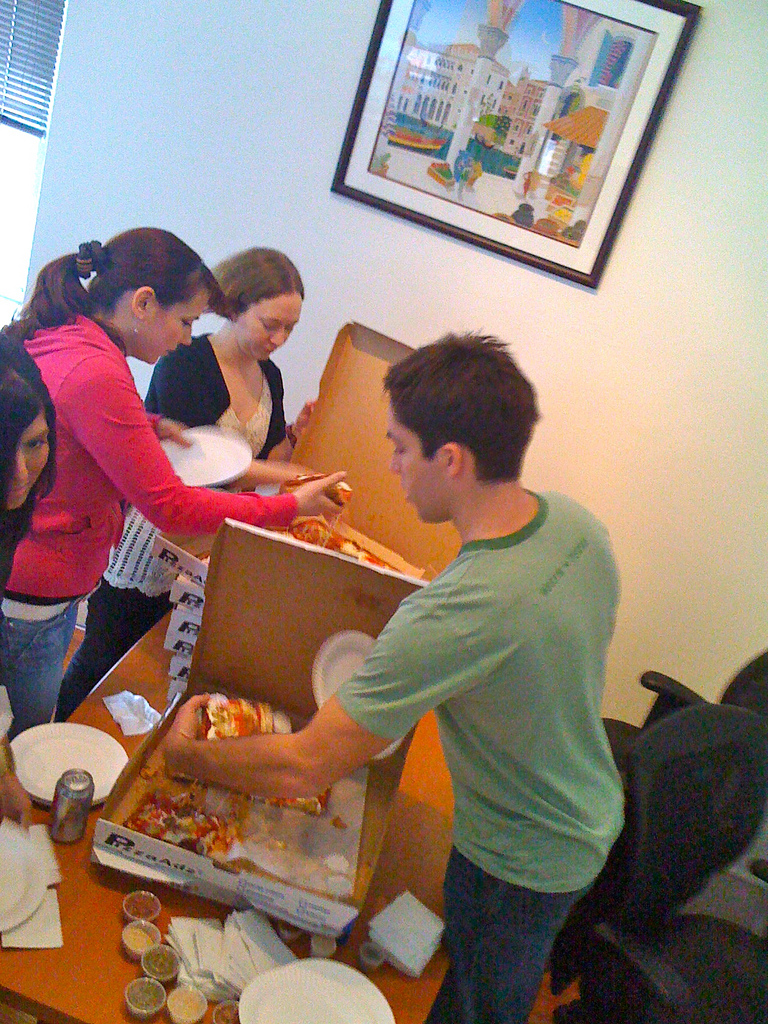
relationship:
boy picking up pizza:
[165, 332, 625, 1022] [170, 657, 309, 862]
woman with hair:
[10, 335, 100, 679] [1, 322, 62, 539]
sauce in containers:
[111, 886, 182, 1001] [92, 890, 263, 1012]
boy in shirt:
[165, 332, 625, 1022] [296, 518, 675, 910]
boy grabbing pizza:
[165, 332, 625, 1022] [145, 657, 348, 837]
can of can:
[29, 747, 121, 879] [51, 767, 95, 839]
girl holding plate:
[0, 227, 352, 744] [156, 420, 271, 517]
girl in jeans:
[0, 210, 275, 778] [7, 576, 118, 729]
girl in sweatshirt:
[0, 210, 275, 778] [8, 294, 331, 623]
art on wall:
[331, 0, 702, 288] [64, 20, 751, 713]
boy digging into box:
[329, 300, 675, 928] [107, 508, 465, 971]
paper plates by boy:
[244, 965, 390, 1016] [165, 332, 625, 1022]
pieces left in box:
[175, 776, 282, 845] [89, 517, 430, 938]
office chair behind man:
[583, 702, 746, 996] [374, 388, 618, 963]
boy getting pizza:
[165, 332, 625, 1022] [136, 684, 282, 820]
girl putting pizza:
[0, 227, 352, 744] [251, 447, 379, 523]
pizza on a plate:
[251, 447, 379, 523] [153, 412, 236, 495]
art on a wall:
[331, 0, 702, 288] [104, 28, 730, 622]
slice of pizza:
[149, 792, 204, 835] [170, 725, 354, 864]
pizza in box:
[170, 725, 354, 864] [115, 669, 457, 948]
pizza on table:
[116, 673, 375, 893] [3, 546, 537, 1022]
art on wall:
[340, 6, 707, 283] [11, 2, 762, 729]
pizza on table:
[124, 692, 332, 862] [3, 546, 537, 1022]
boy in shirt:
[165, 332, 625, 1022] [333, 485, 631, 891]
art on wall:
[331, 0, 702, 288] [11, 2, 762, 729]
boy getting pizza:
[165, 332, 625, 1022] [124, 692, 332, 862]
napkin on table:
[369, 890, 444, 969] [3, 546, 537, 1022]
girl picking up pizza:
[0, 227, 352, 744] [275, 471, 353, 501]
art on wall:
[331, 0, 702, 288] [6, 3, 762, 1004]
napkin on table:
[102, 687, 163, 734] [3, 546, 537, 1022]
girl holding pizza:
[0, 227, 352, 744] [278, 477, 353, 517]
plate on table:
[11, 721, 128, 804] [4, 587, 517, 1021]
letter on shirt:
[549, 570, 557, 583] [333, 485, 631, 891]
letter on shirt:
[555, 561, 568, 581] [333, 485, 631, 891]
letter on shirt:
[571, 540, 582, 556] [333, 485, 631, 891]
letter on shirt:
[564, 547, 583, 570] [333, 485, 631, 891]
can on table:
[51, 767, 95, 839] [6, 610, 461, 1021]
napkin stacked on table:
[367, 889, 446, 979] [6, 610, 461, 1021]